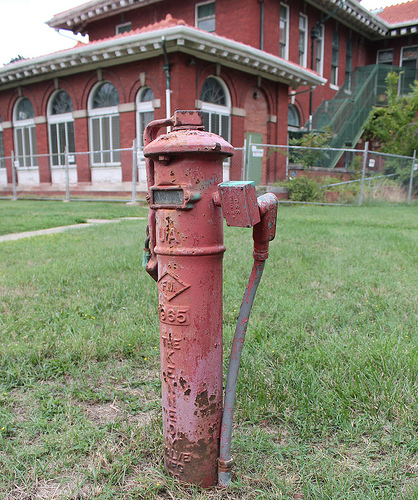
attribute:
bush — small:
[283, 173, 318, 202]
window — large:
[134, 83, 152, 161]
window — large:
[10, 95, 39, 170]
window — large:
[47, 87, 75, 166]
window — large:
[85, 80, 120, 165]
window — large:
[198, 75, 233, 161]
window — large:
[130, 82, 157, 149]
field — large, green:
[9, 192, 416, 470]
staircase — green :
[293, 47, 402, 171]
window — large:
[96, 79, 131, 186]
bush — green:
[280, 164, 331, 209]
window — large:
[79, 79, 120, 170]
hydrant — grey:
[129, 87, 246, 444]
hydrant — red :
[126, 111, 287, 400]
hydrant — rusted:
[144, 109, 272, 489]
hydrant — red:
[137, 112, 285, 484]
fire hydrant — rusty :
[138, 107, 277, 486]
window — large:
[8, 92, 42, 185]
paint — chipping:
[162, 314, 231, 493]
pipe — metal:
[143, 71, 284, 454]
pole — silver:
[7, 146, 20, 202]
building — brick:
[30, 23, 366, 198]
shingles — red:
[79, 13, 204, 38]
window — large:
[208, 71, 221, 127]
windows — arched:
[197, 73, 236, 104]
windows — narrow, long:
[82, 105, 127, 182]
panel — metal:
[144, 177, 207, 211]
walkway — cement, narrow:
[6, 199, 114, 268]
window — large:
[40, 88, 85, 187]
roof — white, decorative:
[4, 13, 317, 83]